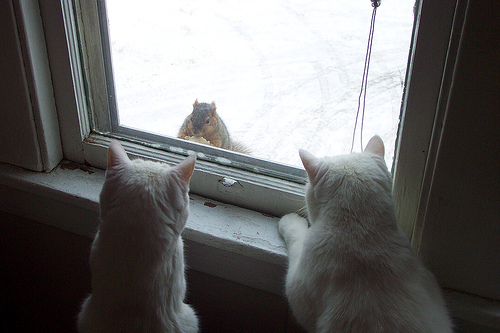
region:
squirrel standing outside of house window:
[172, 94, 252, 158]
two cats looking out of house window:
[68, 130, 465, 331]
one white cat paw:
[275, 208, 311, 240]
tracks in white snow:
[201, 3, 409, 160]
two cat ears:
[100, 135, 200, 190]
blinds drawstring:
[348, 0, 384, 157]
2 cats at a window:
[75, 98, 448, 329]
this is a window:
[29, 14, 466, 289]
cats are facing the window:
[34, 28, 483, 328]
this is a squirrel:
[136, 56, 299, 210]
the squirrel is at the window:
[158, 52, 285, 207]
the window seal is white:
[23, 0, 439, 327]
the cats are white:
[60, 106, 429, 318]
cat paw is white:
[239, 185, 361, 293]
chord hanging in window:
[336, 0, 414, 194]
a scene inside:
[9, 0, 497, 332]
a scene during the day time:
[7, 3, 489, 331]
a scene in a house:
[9, 6, 490, 331]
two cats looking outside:
[33, 121, 473, 332]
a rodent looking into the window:
[145, 88, 259, 176]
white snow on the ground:
[87, 1, 431, 211]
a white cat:
[59, 118, 251, 332]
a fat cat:
[259, 113, 471, 331]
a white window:
[26, 2, 480, 270]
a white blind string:
[340, 0, 388, 182]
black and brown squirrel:
[175, 95, 252, 155]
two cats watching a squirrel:
[73, 95, 454, 331]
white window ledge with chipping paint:
[2, 155, 310, 260]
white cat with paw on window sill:
[274, 134, 456, 331]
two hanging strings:
[345, 0, 386, 162]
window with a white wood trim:
[38, 0, 420, 222]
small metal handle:
[216, 173, 243, 191]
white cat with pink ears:
[76, 140, 203, 331]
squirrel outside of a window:
[40, 0, 420, 209]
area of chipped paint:
[57, 157, 95, 176]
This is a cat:
[67, 140, 229, 317]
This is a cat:
[277, 126, 432, 326]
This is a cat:
[88, 122, 190, 232]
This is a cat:
[278, 134, 390, 224]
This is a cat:
[266, 187, 354, 329]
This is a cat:
[156, 136, 212, 234]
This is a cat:
[97, 127, 154, 221]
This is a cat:
[172, 83, 249, 161]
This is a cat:
[90, 219, 183, 331]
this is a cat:
[269, 122, 454, 332]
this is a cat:
[78, 135, 203, 327]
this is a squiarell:
[166, 93, 243, 157]